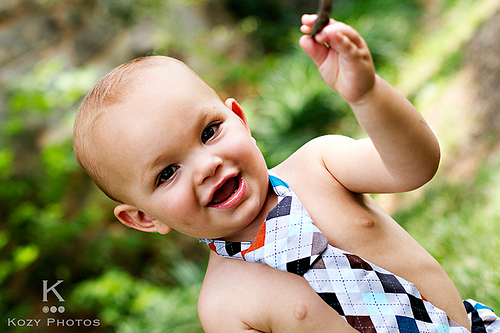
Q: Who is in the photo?
A: Baby boy.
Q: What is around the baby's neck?
A: Tie.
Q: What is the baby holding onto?
A: Stick.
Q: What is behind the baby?
A: Trees.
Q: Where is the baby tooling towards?
A: Camera.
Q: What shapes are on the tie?
A: Diamonds.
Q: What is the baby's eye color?
A: Brown.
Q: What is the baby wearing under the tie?
A: Nothing.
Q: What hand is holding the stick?
A: Left.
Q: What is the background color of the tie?
A: Grey.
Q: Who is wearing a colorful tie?
A: A blonde toddler.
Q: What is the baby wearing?
A: A tie.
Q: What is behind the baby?
A: Grass and trees.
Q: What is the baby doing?
A: Smiling.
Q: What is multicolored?
A: The tie.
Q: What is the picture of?
A: A child.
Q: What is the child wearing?
A: A tie.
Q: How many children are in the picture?
A: One.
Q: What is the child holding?
A: A cigar.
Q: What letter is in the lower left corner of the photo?
A: K.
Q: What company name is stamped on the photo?
A: Kozy Photos.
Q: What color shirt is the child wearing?
A: The child has no shirt.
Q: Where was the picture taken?
A: In a backyard.